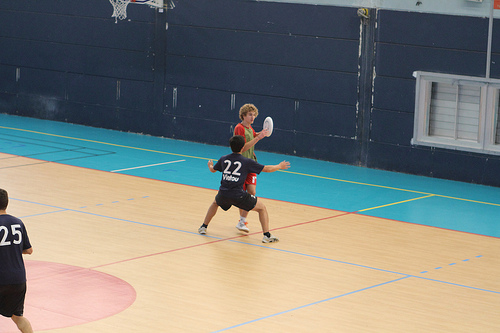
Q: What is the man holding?
A: A frisbee.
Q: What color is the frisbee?
A: White.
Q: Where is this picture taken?
A: A gymnasium.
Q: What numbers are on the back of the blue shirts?
A: 25 and 22.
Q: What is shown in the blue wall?
A: A vent.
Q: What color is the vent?
A: White.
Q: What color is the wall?
A: Blue.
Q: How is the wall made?
A: Of cement blocks.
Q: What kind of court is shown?
A: A basketball court.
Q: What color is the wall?
A: Blue.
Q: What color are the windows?
A: White.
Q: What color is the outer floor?
A: Blue.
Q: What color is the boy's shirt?
A: Black.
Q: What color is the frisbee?
A: White.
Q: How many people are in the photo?
A: 3.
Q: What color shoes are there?
A: White.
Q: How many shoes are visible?
A: 3.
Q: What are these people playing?
A: Ultimate frisbee.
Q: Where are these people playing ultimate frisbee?
A: Indoor basketball court.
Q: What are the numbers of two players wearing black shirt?
A: 22 and 25.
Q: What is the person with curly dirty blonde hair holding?
A: A frisbee.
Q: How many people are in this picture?
A: Three.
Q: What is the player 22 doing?
A: Defending/attempting to block.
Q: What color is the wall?
A: Dark blue.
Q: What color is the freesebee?
A: White.